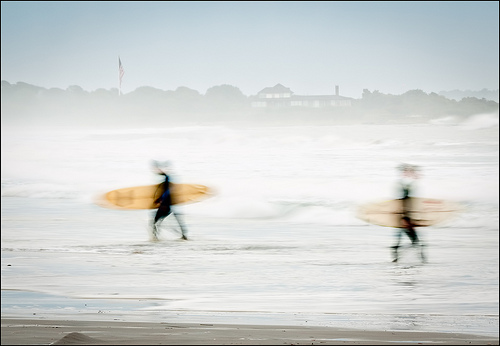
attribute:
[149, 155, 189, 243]
person — surfer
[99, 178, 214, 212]
surfboard — light yellow, yellow, carried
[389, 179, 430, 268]
person — surfer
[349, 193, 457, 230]
surfboard — light yellow, yellow, carried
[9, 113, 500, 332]
sea — wavy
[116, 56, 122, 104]
post — metal, gray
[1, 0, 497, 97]
sky — blue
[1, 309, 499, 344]
sand — wet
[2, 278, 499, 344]
shore — brown, sandy, part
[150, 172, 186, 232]
wetsuit — black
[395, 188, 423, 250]
wetsuit — black